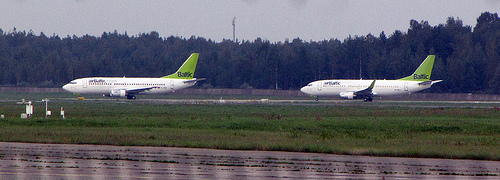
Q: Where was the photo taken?
A: It was taken at the runway.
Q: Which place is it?
A: It is a runway.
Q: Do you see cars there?
A: No, there are no cars.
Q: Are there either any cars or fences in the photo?
A: No, there are no cars or fences.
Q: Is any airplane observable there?
A: Yes, there is an airplane.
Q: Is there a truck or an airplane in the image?
A: Yes, there is an airplane.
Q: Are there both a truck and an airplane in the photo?
A: No, there is an airplane but no trucks.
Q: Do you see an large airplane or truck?
A: Yes, there is a large airplane.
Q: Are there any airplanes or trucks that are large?
A: Yes, the airplane is large.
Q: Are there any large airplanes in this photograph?
A: Yes, there is a large airplane.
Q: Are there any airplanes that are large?
A: Yes, there is an airplane that is large.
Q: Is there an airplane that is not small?
A: Yes, there is a large airplane.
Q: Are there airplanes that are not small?
A: Yes, there is a large airplane.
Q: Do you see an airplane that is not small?
A: Yes, there is a large airplane.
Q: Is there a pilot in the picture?
A: No, there are no pilots.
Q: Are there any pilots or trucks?
A: No, there are no pilots or trucks.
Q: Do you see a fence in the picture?
A: No, there are no fences.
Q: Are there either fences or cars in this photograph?
A: No, there are no fences or cars.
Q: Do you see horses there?
A: No, there are no horses.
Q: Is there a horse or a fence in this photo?
A: No, there are no horses or fences.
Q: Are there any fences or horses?
A: No, there are no horses or fences.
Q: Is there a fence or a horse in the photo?
A: No, there are no horses or fences.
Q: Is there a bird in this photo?
A: No, there are no birds.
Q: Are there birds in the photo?
A: No, there are no birds.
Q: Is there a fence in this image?
A: No, there are no fences.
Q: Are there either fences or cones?
A: No, there are no fences or cones.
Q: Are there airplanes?
A: Yes, there is an airplane.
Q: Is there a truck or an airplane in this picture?
A: Yes, there is an airplane.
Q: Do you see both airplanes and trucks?
A: No, there is an airplane but no trucks.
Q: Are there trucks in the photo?
A: No, there are no trucks.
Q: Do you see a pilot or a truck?
A: No, there are no trucks or pilots.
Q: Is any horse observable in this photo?
A: No, there are no horses.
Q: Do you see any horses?
A: No, there are no horses.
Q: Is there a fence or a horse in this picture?
A: No, there are no horses or fences.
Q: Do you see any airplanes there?
A: Yes, there is an airplane.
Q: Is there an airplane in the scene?
A: Yes, there is an airplane.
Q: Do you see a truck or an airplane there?
A: Yes, there is an airplane.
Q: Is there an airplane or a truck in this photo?
A: Yes, there is an airplane.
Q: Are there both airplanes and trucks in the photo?
A: No, there is an airplane but no trucks.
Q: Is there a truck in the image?
A: No, there are no trucks.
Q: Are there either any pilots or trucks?
A: No, there are no trucks or pilots.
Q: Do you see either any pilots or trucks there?
A: No, there are no trucks or pilots.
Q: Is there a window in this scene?
A: Yes, there are windows.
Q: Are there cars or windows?
A: Yes, there are windows.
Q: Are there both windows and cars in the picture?
A: No, there are windows but no cars.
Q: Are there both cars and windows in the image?
A: No, there are windows but no cars.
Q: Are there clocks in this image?
A: No, there are no clocks.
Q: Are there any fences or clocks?
A: No, there are no clocks or fences.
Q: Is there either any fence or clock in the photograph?
A: No, there are no clocks or fences.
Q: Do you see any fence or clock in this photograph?
A: No, there are no clocks or fences.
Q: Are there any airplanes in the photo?
A: Yes, there is an airplane.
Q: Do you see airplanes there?
A: Yes, there is an airplane.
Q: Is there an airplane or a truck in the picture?
A: Yes, there is an airplane.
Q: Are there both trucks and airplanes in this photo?
A: No, there is an airplane but no trucks.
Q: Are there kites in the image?
A: No, there are no kites.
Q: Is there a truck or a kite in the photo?
A: No, there are no kites or trucks.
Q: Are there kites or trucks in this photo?
A: No, there are no kites or trucks.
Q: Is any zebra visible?
A: No, there are no zebras.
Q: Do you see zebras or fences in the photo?
A: No, there are no zebras or fences.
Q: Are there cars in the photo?
A: No, there are no cars.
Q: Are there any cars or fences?
A: No, there are no cars or fences.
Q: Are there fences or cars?
A: No, there are no cars or fences.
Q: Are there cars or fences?
A: No, there are no cars or fences.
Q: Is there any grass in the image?
A: Yes, there is grass.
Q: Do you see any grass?
A: Yes, there is grass.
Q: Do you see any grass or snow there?
A: Yes, there is grass.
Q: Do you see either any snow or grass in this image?
A: Yes, there is grass.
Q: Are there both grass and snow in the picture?
A: No, there is grass but no snow.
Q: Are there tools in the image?
A: No, there are no tools.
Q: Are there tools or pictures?
A: No, there are no tools or pictures.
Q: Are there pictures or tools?
A: No, there are no tools or pictures.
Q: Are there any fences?
A: No, there are no fences.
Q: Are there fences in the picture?
A: No, there are no fences.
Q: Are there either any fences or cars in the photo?
A: No, there are no fences or cars.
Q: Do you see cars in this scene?
A: No, there are no cars.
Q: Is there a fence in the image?
A: No, there are no fences.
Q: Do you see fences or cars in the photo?
A: No, there are no cars or fences.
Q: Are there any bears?
A: No, there are no bears.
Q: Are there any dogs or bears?
A: No, there are no bears or dogs.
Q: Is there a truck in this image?
A: No, there are no trucks.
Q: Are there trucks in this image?
A: No, there are no trucks.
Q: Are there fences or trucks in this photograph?
A: No, there are no trucks or fences.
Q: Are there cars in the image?
A: No, there are no cars.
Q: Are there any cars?
A: No, there are no cars.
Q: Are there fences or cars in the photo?
A: No, there are no cars or fences.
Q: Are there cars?
A: No, there are no cars.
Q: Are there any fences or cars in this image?
A: No, there are no cars or fences.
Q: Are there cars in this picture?
A: No, there are no cars.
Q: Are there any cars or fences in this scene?
A: No, there are no cars or fences.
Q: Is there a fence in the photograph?
A: No, there are no fences.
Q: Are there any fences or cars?
A: No, there are no fences or cars.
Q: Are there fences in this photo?
A: No, there are no fences.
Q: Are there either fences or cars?
A: No, there are no fences or cars.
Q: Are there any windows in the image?
A: Yes, there are windows.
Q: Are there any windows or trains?
A: Yes, there are windows.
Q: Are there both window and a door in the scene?
A: No, there are windows but no doors.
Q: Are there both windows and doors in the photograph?
A: No, there are windows but no doors.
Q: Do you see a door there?
A: No, there are no doors.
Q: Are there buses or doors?
A: No, there are no doors or buses.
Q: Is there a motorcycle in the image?
A: Yes, there is a motorcycle.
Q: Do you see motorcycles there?
A: Yes, there is a motorcycle.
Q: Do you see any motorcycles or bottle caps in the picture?
A: Yes, there is a motorcycle.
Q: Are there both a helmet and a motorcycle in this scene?
A: No, there is a motorcycle but no helmets.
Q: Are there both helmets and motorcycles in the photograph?
A: No, there is a motorcycle but no helmets.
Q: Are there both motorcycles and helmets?
A: No, there is a motorcycle but no helmets.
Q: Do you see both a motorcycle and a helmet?
A: No, there is a motorcycle but no helmets.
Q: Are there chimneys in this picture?
A: No, there are no chimneys.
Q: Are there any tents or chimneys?
A: No, there are no chimneys or tents.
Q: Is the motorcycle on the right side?
A: Yes, the motorcycle is on the right of the image.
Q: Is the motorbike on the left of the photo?
A: No, the motorbike is on the right of the image.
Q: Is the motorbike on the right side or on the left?
A: The motorbike is on the right of the image.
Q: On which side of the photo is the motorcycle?
A: The motorcycle is on the right of the image.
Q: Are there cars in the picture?
A: No, there are no cars.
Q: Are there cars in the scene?
A: No, there are no cars.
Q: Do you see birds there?
A: No, there are no birds.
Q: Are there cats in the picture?
A: No, there are no cats.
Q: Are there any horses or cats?
A: No, there are no cats or horses.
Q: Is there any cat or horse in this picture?
A: No, there are no cats or horses.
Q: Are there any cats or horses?
A: No, there are no cats or horses.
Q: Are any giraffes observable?
A: No, there are no giraffes.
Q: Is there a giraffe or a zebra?
A: No, there are no giraffes or zebras.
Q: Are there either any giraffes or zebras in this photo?
A: No, there are no giraffes or zebras.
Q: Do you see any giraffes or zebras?
A: No, there are no giraffes or zebras.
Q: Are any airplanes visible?
A: Yes, there is an airplane.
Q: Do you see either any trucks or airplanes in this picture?
A: Yes, there is an airplane.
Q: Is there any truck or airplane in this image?
A: Yes, there is an airplane.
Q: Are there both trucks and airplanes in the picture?
A: No, there is an airplane but no trucks.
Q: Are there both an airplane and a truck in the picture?
A: No, there is an airplane but no trucks.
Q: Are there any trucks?
A: No, there are no trucks.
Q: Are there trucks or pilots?
A: No, there are no trucks or pilots.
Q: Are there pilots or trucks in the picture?
A: No, there are no trucks or pilots.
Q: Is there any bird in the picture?
A: No, there are no birds.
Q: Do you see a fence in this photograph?
A: No, there are no fences.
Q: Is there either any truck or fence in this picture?
A: No, there are no fences or trucks.